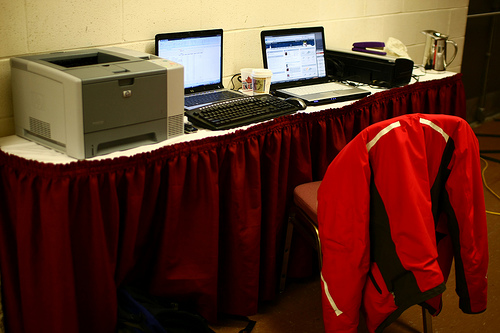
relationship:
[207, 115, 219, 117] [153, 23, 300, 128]
black key on computer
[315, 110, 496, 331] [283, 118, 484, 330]
jacket on a chair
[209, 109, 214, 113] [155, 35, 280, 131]
key on computer